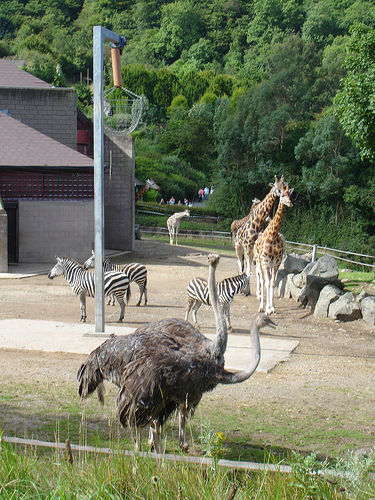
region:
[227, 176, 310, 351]
two giraffes close together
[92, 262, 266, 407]
two emu close together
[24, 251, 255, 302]
three zebra close together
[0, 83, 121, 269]
large grey stone building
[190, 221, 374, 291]
wooden fence in distance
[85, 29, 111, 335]
tall steel pole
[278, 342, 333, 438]
ground is grey and bare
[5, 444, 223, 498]
tall grasses near fence in front of emu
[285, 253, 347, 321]
stones near two giraffes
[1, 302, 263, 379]
pole on concrete base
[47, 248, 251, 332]
zebras roaming at a zoo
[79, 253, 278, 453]
ostriches roaming at a zoo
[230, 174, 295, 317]
giraffes roaming at a zoo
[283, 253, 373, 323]
rocks in an animal enclosure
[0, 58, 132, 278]
a building located in an animal enclosure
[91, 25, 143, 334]
a pole with a basket attached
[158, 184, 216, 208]
people walking zoo grounds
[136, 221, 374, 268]
fencing around animal enclosure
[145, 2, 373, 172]
trees surround animal enclosure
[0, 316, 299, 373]
concrete pad in animal enclosure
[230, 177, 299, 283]
three giraffes are standing in the park.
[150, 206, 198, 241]
a giraffe is looking at the grass.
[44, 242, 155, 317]
two black stripped zebras are standing by a pole.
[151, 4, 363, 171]
a back round of beautiful trees.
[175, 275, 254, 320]
a zebra is next to the giraffes.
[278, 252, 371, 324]
a bunch of huge rocks.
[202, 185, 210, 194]
a man is wearing a light blue shirt.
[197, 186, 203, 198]
a woman is wearing a red shirt.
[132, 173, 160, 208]
a giraffe is sticking its head out from the building.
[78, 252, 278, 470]
two ostriches enjoying the weather.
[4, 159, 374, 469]
African animals in a zoo enclosure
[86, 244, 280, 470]
two ostriches in a zoo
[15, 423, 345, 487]
wooden plank fence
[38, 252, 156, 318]
two zebras in a zoo pen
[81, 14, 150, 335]
metal light post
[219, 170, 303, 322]
two giraffes standing in pen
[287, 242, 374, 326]
collection of rocks in pen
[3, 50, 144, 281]
large building inside zoo enclosure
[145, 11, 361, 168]
trees with light and dark green leaves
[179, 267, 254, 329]
small zebra standing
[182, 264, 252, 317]
black and white zebra next to giraffes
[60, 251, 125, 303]
black and white zebra next to a pole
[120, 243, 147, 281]
black and white zebra next to another zebra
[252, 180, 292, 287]
tall brown giraffe next to rocks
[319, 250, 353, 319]
rocks next to a giraffe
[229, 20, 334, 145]
green trees in a zoo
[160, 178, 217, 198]
people walking in a zoo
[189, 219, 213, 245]
fence inside of a zoo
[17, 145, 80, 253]
large brick house for animals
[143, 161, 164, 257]
large giraffe behind a house